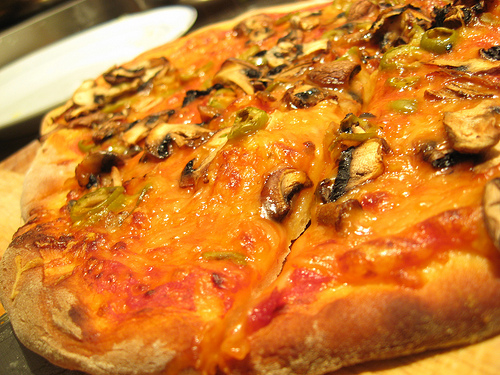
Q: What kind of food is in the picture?
A: A pizza.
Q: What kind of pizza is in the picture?
A: Mushroom and green olive pizza.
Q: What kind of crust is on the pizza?
A: A brown, baked crust.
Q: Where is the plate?
A: Behind the pizza.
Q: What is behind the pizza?
A: A white plate.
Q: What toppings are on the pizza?
A: Sauce, cheese, mushrooms, and green olives.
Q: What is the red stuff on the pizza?
A: Tomato sauce.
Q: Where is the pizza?
A: On a table.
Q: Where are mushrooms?
A: On pizza.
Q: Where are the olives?
A: On pizza.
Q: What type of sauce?
A: Tomato.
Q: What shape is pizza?
A: Round.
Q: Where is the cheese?
A: On pizza.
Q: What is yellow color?
A: Cheese.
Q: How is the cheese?
A: Melted.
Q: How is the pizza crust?
A: Thick.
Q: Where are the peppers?
A: On pizza.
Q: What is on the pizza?
A: Mushrooms.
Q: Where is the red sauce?
A: On the pizza.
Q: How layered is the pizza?
A: Multi.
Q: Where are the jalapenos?
A: On the pizza.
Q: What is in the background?
A: White plate.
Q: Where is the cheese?
A: On the pizza.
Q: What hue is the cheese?
A: Orange.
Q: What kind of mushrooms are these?
A: Small mushrooms.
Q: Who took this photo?
A: Jackson Mingus.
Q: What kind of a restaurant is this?
A: An Italian restaurant.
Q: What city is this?
A: Chicago.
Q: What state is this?
A: Illinois.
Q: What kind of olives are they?
A: Green olives.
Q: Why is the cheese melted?
A: It is hot.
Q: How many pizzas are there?
A: One.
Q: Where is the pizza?
A: On a cutting board.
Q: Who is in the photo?
A: Nobody.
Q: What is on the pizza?
A: Mushrooms.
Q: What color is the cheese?
A: Yellow.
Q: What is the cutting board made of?
A: Wood.